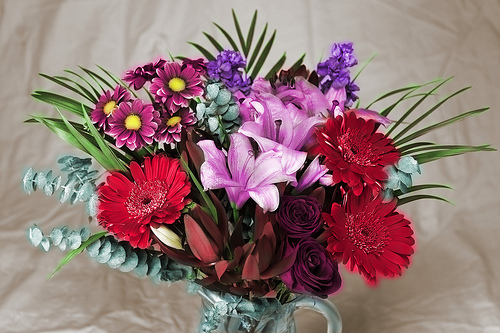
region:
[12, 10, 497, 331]
a flower arrangement in a glass jug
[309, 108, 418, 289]
two red Gerbera in a flower arrangement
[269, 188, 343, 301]
deep purple roses in a bouquet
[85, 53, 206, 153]
purple and yellow Chrysanthemums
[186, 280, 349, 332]
a glass jug with a handle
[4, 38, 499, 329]
white fabric behind a floral display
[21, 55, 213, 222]
green foliage in a bunch of flowers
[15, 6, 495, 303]
a bouquet of fresh flowers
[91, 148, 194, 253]
a deep red Gerbera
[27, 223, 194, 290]
grey-green foliage in a bouquet of flowers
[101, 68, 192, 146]
inside of flowers are yellow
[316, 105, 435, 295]
the flowers are red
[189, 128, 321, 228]
the flower is pink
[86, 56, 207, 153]
the flowers are purple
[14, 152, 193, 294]
the flowers are green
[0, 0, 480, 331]
flowers are in a vase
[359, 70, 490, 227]
leaves behind the flowers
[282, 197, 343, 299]
flowers have a swirl pattern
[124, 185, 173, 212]
white spots inside flower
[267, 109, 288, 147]
purple stem inside flower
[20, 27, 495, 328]
wrinkled white background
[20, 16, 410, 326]
bouquet of flowers in silver pitcher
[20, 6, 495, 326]
combination of floral shapes and colors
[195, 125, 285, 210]
pointy purple petals curving outwards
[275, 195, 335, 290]
small and tight clusters of maroon petals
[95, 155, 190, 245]
oval red petals around fuzzy red and white circle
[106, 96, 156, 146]
white edges on purple petals with yellow center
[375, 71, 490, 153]
thin and long green blades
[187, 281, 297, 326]
embellished rim of leaves and petals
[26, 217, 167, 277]
round powdery green leaves in a stack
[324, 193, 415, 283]
pink flower in vase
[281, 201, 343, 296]
purple roses in vase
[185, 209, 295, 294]
maroon flowers in vase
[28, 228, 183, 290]
blue plant in vase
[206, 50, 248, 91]
purple flowers in vase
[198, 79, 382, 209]
lavender flowers in vase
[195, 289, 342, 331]
blue ceramic pitcher vase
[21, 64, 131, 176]
green leaves in vase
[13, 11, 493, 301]
flowers in blue vase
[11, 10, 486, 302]
multi colored flowers in vase